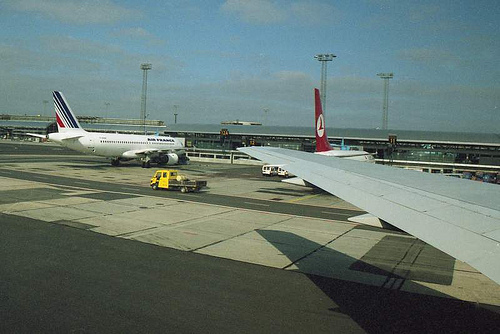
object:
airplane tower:
[36, 100, 50, 120]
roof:
[5, 100, 495, 164]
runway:
[0, 158, 499, 334]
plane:
[45, 87, 187, 181]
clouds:
[0, 2, 499, 136]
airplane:
[313, 87, 375, 161]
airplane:
[26, 90, 191, 169]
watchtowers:
[313, 52, 340, 62]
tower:
[376, 72, 401, 131]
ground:
[389, 153, 418, 189]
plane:
[234, 142, 499, 284]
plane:
[21, 81, 185, 165]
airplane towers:
[140, 64, 154, 126]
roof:
[11, 112, 498, 170]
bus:
[261, 164, 278, 176]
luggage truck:
[149, 169, 206, 194]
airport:
[0, 0, 499, 332]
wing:
[313, 87, 334, 152]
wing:
[236, 146, 499, 284]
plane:
[294, 85, 375, 183]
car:
[277, 167, 290, 177]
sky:
[0, 6, 499, 131]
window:
[98, 137, 102, 143]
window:
[104, 135, 107, 143]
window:
[116, 139, 121, 144]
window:
[137, 140, 142, 145]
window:
[156, 140, 162, 144]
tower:
[309, 53, 338, 121]